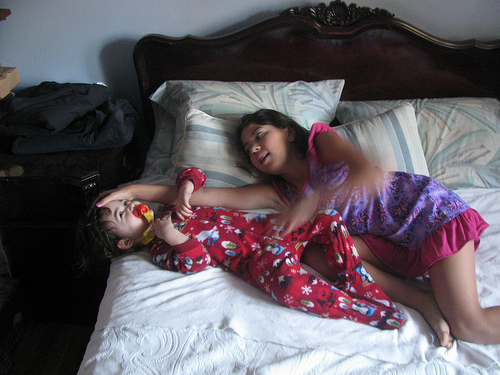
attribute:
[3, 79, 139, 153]
sheet — black 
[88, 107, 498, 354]
girl — in the picture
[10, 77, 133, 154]
sheet — Dark 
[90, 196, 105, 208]
nail — pink 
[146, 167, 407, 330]
pajamas — red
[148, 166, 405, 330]
one piece — red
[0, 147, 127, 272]
dark table — brown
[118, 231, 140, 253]
ear — in the picture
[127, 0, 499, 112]
headboard — brown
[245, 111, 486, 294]
dress — in the picture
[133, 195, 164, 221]
pacifier — red 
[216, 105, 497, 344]
girl — in the picture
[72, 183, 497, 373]
spread — white 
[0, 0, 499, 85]
wall — white 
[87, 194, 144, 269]
hair — brown 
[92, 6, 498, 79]
headboard — brown 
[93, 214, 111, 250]
hair — short 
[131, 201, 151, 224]
pacifier — yellow 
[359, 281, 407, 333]
foot — in the picture